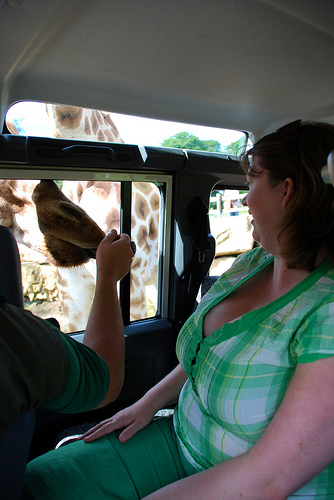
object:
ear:
[282, 178, 294, 208]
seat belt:
[177, 196, 216, 331]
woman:
[25, 116, 333, 500]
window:
[1, 178, 161, 338]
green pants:
[25, 413, 202, 500]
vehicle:
[1, 0, 332, 499]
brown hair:
[235, 118, 334, 276]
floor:
[133, 76, 198, 107]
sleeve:
[33, 316, 111, 411]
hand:
[95, 227, 132, 282]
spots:
[134, 193, 150, 224]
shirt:
[172, 246, 333, 500]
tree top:
[159, 131, 223, 153]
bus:
[1, 0, 332, 498]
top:
[0, 0, 331, 148]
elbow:
[95, 370, 125, 410]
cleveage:
[205, 301, 262, 337]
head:
[0, 118, 108, 269]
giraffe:
[0, 102, 160, 335]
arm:
[0, 284, 126, 414]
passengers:
[0, 103, 333, 498]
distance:
[208, 180, 328, 473]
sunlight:
[5, 101, 253, 160]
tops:
[165, 129, 221, 149]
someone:
[0, 227, 137, 500]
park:
[0, 98, 256, 339]